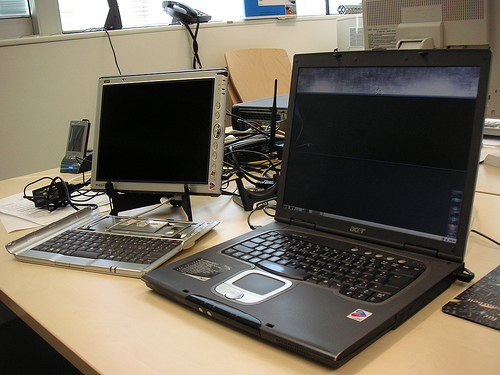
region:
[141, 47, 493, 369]
a black laptop computer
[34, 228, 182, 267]
a black computer keyboard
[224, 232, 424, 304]
a black computer keyboard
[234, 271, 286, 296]
a computer keyboard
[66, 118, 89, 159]
a small cell phone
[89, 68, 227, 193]
a silver computer monitor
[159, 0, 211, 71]
a black telephone handset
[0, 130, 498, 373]
a beige computer desk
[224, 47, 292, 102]
a light wood chair back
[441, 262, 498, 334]
a computer mouse pad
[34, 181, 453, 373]
Two keyboards are on the desk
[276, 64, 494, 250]
The screen is black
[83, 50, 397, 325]
The monitor is off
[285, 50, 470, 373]
This is a laptop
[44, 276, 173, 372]
The desk is made of wood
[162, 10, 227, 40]
The telephone is on the desk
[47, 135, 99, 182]
The charger is on the table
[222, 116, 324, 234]
The cords are behind the computer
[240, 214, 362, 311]
The keyboard is black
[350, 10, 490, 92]
A keyboard is behind the laptop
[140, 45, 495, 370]
Opened black laptop computer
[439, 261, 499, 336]
Corner edge of a computer mouse pad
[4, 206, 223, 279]
Detached computer keyboard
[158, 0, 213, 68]
A desktop telephone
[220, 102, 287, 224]
Pile of messy wires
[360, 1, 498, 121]
Backside of a grey computer screen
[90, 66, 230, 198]
Detached computer screen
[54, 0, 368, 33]
Bottom portion of a window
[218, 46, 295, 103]
Top of a light brown wood chair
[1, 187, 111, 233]
Two peices of paper on a desk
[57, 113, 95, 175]
cell phone is charger base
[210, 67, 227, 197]
control buttons on side of monitor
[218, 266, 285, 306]
mouse pad and controller on laptop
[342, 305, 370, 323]
logo label on laptop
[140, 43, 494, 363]
black laptop on table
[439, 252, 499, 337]
mouse pad to right of laptop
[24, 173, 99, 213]
wadded up power cord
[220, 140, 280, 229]
wadded up headset and cords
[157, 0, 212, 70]
standard phone on window sill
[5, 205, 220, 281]
small laptop plugged to monitor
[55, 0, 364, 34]
office window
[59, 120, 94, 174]
silver cell phone in a charging dock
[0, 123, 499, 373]
light wooden desk top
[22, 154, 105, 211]
laptops black power chords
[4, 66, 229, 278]
silver convertible laptop / tablet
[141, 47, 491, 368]
black acer brand laptop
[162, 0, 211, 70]
black corded land line phone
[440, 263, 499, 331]
plastic mouse pad showing a city scape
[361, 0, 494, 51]
back of a large computer monitor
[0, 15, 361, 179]
white painted half wall